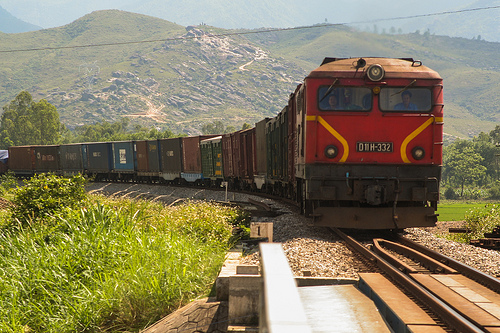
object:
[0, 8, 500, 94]
mountains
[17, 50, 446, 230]
train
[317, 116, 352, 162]
stripe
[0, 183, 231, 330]
grass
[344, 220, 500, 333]
tracks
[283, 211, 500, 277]
gravel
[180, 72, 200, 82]
rocks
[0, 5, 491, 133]
hill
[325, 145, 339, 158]
headlights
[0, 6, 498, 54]
wire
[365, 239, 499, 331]
trestle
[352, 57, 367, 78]
horn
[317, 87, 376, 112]
windows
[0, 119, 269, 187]
freight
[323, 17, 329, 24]
tower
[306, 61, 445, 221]
engine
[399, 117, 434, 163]
stripes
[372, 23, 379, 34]
tree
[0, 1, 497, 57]
distance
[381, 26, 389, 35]
tree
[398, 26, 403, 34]
tree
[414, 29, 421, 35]
tree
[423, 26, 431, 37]
tree